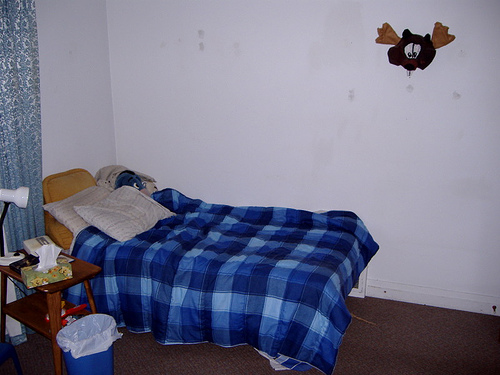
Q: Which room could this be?
A: It is a bedroom.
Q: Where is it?
A: This is at the bedroom.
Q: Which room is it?
A: It is a bedroom.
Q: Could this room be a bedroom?
A: Yes, it is a bedroom.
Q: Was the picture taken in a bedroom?
A: Yes, it was taken in a bedroom.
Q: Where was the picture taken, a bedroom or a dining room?
A: It was taken at a bedroom.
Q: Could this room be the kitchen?
A: No, it is the bedroom.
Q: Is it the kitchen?
A: No, it is the bedroom.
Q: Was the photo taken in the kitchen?
A: No, the picture was taken in the bedroom.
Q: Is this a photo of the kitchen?
A: No, the picture is showing the bedroom.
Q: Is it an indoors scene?
A: Yes, it is indoors.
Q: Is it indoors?
A: Yes, it is indoors.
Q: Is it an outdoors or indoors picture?
A: It is indoors.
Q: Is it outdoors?
A: No, it is indoors.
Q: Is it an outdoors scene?
A: No, it is indoors.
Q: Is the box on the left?
A: Yes, the box is on the left of the image.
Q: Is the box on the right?
A: No, the box is on the left of the image.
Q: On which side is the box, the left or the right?
A: The box is on the left of the image.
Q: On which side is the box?
A: The box is on the left of the image.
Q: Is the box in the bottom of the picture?
A: Yes, the box is in the bottom of the image.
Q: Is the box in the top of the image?
A: No, the box is in the bottom of the image.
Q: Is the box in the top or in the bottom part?
A: The box is in the bottom of the image.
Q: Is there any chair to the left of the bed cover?
A: No, there is a box to the left of the bed cover.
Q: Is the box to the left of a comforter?
A: Yes, the box is to the left of a comforter.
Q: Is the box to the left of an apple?
A: No, the box is to the left of a comforter.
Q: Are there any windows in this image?
A: Yes, there is a window.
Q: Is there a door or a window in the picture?
A: Yes, there is a window.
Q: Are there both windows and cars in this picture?
A: No, there is a window but no cars.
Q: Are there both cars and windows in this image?
A: No, there is a window but no cars.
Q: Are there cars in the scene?
A: No, there are no cars.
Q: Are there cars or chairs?
A: No, there are no cars or chairs.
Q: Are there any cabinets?
A: No, there are no cabinets.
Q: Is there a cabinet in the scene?
A: No, there are no cabinets.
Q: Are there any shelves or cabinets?
A: No, there are no cabinets or shelves.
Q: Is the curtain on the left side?
A: Yes, the curtain is on the left of the image.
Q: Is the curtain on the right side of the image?
A: No, the curtain is on the left of the image.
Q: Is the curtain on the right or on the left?
A: The curtain is on the left of the image.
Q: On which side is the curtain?
A: The curtain is on the left of the image.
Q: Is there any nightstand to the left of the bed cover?
A: No, there is a curtain to the left of the bed cover.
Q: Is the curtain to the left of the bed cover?
A: Yes, the curtain is to the left of the bed cover.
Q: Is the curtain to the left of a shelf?
A: No, the curtain is to the left of the bed cover.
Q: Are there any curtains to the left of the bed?
A: Yes, there is a curtain to the left of the bed.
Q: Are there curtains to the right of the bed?
A: No, the curtain is to the left of the bed.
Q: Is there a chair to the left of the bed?
A: No, there is a curtain to the left of the bed.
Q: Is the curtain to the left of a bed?
A: Yes, the curtain is to the left of a bed.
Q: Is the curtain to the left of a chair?
A: No, the curtain is to the left of a bed.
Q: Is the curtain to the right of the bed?
A: No, the curtain is to the left of the bed.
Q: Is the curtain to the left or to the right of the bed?
A: The curtain is to the left of the bed.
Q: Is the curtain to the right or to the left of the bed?
A: The curtain is to the left of the bed.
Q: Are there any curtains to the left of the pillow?
A: Yes, there is a curtain to the left of the pillow.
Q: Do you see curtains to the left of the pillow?
A: Yes, there is a curtain to the left of the pillow.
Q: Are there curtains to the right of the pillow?
A: No, the curtain is to the left of the pillow.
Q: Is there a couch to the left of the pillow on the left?
A: No, there is a curtain to the left of the pillow.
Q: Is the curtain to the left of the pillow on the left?
A: Yes, the curtain is to the left of the pillow.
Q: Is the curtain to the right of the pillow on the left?
A: No, the curtain is to the left of the pillow.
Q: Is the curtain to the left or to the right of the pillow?
A: The curtain is to the left of the pillow.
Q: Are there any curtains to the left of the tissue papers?
A: Yes, there is a curtain to the left of the tissue papers.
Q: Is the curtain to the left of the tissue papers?
A: Yes, the curtain is to the left of the tissue papers.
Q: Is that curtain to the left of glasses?
A: No, the curtain is to the left of the tissue papers.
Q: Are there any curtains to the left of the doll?
A: Yes, there is a curtain to the left of the doll.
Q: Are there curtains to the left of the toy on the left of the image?
A: Yes, there is a curtain to the left of the doll.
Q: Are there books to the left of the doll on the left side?
A: No, there is a curtain to the left of the doll.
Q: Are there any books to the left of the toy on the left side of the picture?
A: No, there is a curtain to the left of the doll.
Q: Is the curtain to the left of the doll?
A: Yes, the curtain is to the left of the doll.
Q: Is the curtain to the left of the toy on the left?
A: Yes, the curtain is to the left of the doll.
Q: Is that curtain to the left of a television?
A: No, the curtain is to the left of the doll.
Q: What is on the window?
A: The curtain is on the window.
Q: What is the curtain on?
A: The curtain is on the window.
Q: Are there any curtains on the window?
A: Yes, there is a curtain on the window.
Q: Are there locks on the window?
A: No, there is a curtain on the window.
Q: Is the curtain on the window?
A: Yes, the curtain is on the window.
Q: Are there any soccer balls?
A: No, there are no soccer balls.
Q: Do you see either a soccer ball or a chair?
A: No, there are no soccer balls or chairs.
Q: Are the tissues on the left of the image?
A: Yes, the tissues are on the left of the image.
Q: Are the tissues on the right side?
A: No, the tissues are on the left of the image.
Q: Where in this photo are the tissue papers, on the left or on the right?
A: The tissue papers are on the left of the image.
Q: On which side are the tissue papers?
A: The tissue papers are on the left of the image.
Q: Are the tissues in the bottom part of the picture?
A: Yes, the tissues are in the bottom of the image.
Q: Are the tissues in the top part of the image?
A: No, the tissues are in the bottom of the image.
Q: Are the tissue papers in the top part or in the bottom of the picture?
A: The tissue papers are in the bottom of the image.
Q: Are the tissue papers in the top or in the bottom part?
A: The tissue papers are in the bottom of the image.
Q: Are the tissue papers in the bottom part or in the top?
A: The tissue papers are in the bottom of the image.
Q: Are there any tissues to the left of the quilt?
A: Yes, there are tissues to the left of the quilt.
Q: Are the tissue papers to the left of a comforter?
A: Yes, the tissue papers are to the left of a comforter.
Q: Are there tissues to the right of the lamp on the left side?
A: Yes, there are tissues to the right of the lamp.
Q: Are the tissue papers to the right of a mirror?
A: No, the tissue papers are to the right of the lamp.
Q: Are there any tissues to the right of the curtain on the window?
A: Yes, there are tissues to the right of the curtain.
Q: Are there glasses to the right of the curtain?
A: No, there are tissues to the right of the curtain.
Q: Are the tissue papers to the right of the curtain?
A: Yes, the tissue papers are to the right of the curtain.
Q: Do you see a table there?
A: Yes, there is a table.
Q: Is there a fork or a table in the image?
A: Yes, there is a table.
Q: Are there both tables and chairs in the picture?
A: No, there is a table but no chairs.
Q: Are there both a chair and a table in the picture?
A: No, there is a table but no chairs.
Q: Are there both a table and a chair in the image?
A: No, there is a table but no chairs.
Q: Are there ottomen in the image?
A: No, there are no ottomen.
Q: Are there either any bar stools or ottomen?
A: No, there are no ottomen or bar stools.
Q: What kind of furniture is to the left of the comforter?
A: The piece of furniture is a table.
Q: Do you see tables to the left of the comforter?
A: Yes, there is a table to the left of the comforter.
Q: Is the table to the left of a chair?
A: No, the table is to the left of the quilt.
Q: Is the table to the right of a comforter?
A: No, the table is to the left of a comforter.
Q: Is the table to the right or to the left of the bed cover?
A: The table is to the left of the bed cover.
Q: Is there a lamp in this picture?
A: Yes, there is a lamp.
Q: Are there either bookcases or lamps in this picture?
A: Yes, there is a lamp.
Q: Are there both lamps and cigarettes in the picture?
A: No, there is a lamp but no cigarettes.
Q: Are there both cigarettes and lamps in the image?
A: No, there is a lamp but no cigarettes.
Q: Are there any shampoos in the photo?
A: No, there are no shampoos.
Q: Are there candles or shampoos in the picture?
A: No, there are no shampoos or candles.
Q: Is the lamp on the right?
A: No, the lamp is on the left of the image.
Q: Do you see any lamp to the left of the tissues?
A: Yes, there is a lamp to the left of the tissues.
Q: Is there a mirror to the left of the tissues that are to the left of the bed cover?
A: No, there is a lamp to the left of the tissues.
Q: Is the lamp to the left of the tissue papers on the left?
A: Yes, the lamp is to the left of the tissues.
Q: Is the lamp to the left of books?
A: No, the lamp is to the left of the tissues.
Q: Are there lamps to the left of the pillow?
A: Yes, there is a lamp to the left of the pillow.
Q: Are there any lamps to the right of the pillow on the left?
A: No, the lamp is to the left of the pillow.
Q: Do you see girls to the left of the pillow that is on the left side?
A: No, there is a lamp to the left of the pillow.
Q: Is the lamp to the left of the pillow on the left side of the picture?
A: Yes, the lamp is to the left of the pillow.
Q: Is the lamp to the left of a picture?
A: No, the lamp is to the left of the pillow.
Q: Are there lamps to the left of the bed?
A: Yes, there is a lamp to the left of the bed.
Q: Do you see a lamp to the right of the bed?
A: No, the lamp is to the left of the bed.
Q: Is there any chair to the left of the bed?
A: No, there is a lamp to the left of the bed.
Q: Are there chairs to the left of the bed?
A: No, there is a lamp to the left of the bed.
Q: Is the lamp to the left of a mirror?
A: No, the lamp is to the left of a bed.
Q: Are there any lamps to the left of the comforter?
A: Yes, there is a lamp to the left of the comforter.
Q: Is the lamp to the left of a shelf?
A: No, the lamp is to the left of the quilt.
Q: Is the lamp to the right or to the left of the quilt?
A: The lamp is to the left of the quilt.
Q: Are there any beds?
A: Yes, there is a bed.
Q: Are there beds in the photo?
A: Yes, there is a bed.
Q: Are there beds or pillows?
A: Yes, there is a bed.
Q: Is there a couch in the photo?
A: No, there are no couches.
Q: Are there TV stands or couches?
A: No, there are no couches or TV stands.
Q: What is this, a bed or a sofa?
A: This is a bed.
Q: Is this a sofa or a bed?
A: This is a bed.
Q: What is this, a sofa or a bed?
A: This is a bed.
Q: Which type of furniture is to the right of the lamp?
A: The piece of furniture is a bed.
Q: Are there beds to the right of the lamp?
A: Yes, there is a bed to the right of the lamp.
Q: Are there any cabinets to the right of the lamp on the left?
A: No, there is a bed to the right of the lamp.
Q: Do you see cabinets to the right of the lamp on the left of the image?
A: No, there is a bed to the right of the lamp.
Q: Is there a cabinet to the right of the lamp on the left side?
A: No, there is a bed to the right of the lamp.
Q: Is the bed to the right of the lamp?
A: Yes, the bed is to the right of the lamp.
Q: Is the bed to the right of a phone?
A: No, the bed is to the right of the lamp.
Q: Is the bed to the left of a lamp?
A: No, the bed is to the right of a lamp.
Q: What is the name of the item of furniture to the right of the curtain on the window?
A: The piece of furniture is a bed.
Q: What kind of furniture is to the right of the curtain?
A: The piece of furniture is a bed.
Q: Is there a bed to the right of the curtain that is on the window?
A: Yes, there is a bed to the right of the curtain.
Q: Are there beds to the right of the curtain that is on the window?
A: Yes, there is a bed to the right of the curtain.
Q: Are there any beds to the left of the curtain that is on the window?
A: No, the bed is to the right of the curtain.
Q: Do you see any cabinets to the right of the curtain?
A: No, there is a bed to the right of the curtain.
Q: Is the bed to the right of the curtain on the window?
A: Yes, the bed is to the right of the curtain.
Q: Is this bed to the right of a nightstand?
A: No, the bed is to the right of the curtain.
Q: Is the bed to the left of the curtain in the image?
A: No, the bed is to the right of the curtain.